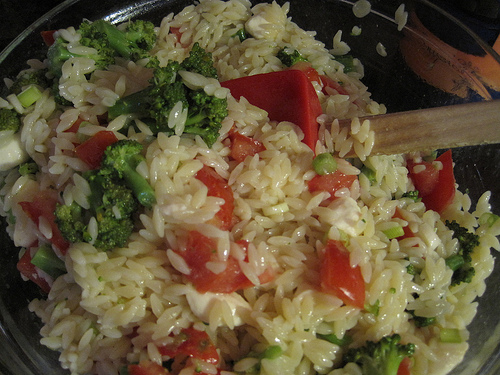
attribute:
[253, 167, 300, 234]
rice grains — white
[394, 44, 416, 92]
glass — transparent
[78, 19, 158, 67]
broccoli — green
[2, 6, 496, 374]
bowl — glass, red, full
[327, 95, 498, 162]
spoon — wooden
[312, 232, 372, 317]
tomato — red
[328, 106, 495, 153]
handle — wooden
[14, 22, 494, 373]
rice — cooked, wet